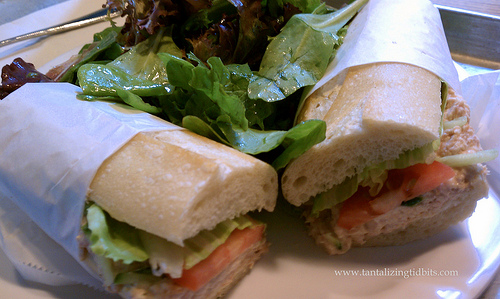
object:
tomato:
[170, 224, 263, 292]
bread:
[278, 1, 443, 208]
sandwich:
[280, 0, 499, 257]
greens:
[157, 64, 233, 110]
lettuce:
[84, 204, 150, 264]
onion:
[145, 240, 183, 278]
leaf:
[0, 57, 52, 93]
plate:
[0, 0, 499, 298]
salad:
[112, 4, 238, 73]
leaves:
[246, 0, 367, 103]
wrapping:
[0, 82, 190, 284]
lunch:
[0, 0, 499, 299]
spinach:
[301, 0, 334, 17]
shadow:
[277, 225, 306, 251]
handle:
[0, 5, 128, 47]